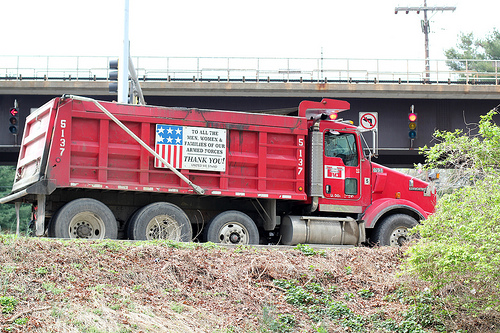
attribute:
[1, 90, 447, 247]
truck — red, lorry, empty, dump truck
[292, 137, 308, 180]
numbers — white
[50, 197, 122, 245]
tire — wheel, black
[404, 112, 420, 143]
signal — traffic signal, traffic light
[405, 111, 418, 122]
light — red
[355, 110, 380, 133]
sign — no left turn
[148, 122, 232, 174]
sign — white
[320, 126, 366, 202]
door — red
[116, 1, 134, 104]
pole — existing, white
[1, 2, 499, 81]
sky — existing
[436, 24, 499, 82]
tree — existing, green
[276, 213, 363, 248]
tank — silver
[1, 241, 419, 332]
grass — brown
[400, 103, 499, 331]
shrub — green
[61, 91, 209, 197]
bar — metal, white